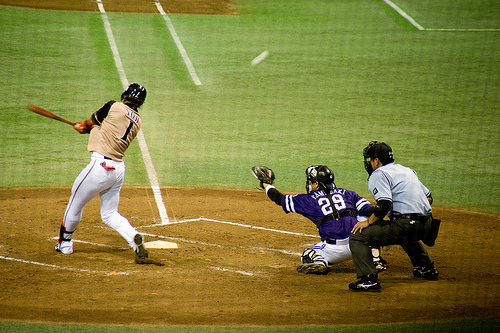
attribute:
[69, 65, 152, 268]
player — swinging, playing, close, batting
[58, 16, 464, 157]
field — green, brown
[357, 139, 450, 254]
umpire — white, sitting, watching, looking, calling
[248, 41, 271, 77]
baseball — white, flying, round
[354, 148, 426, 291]
umpire — crouching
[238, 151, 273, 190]
mit — black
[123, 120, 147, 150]
player number — one